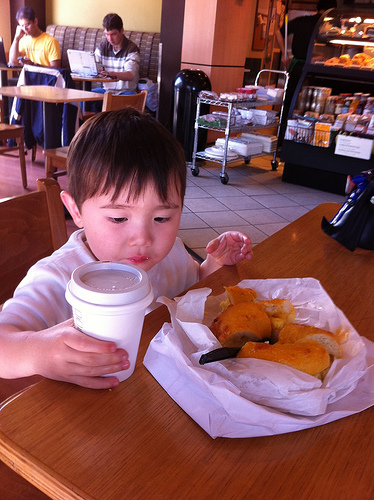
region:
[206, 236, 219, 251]
small child's left thumb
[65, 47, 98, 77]
rear of laptop monitor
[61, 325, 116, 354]
small child's index finger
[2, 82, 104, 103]
small dining table top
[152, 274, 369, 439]
crumpled paper food bag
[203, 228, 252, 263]
small child's left hand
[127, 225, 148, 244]
small asian child's nose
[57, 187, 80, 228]
small child's right ear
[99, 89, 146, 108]
rear of wooden chair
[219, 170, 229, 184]
small black cart wheel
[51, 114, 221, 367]
boy is holding a cup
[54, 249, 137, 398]
the cup has lid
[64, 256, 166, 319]
the lid is white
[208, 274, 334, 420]
bread on the paper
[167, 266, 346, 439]
food on the table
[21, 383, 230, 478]
the table is wooden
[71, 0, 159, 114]
man is using a laptop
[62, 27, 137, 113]
laptop on the table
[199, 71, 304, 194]
containers in the cart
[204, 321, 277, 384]
bread knife is black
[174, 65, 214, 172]
A black shiny garbage bin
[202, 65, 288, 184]
A silver food cart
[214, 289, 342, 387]
A sandwhich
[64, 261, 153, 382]
A white sip cup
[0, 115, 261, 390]
A young boy in a white shirt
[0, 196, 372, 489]
A wooden shiny dinner table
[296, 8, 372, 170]
Refrigerated food stuff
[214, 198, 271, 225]
Grey tile floor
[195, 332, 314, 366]
A serrated knife for cutting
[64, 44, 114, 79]
A laptop computer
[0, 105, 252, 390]
Child holding white cup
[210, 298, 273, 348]
Bread on white bag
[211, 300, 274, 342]
Bread next to bread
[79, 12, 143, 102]
Man on laptop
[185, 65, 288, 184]
Silver metal cart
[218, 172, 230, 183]
Small black wheel on silver metal cart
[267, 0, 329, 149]
Person wearing black shirt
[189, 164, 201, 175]
Small black wheel on silver metal cart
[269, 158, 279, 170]
Small black wheel on silver metal cart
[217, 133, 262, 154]
White box on silver metal cart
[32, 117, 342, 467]
a kid taking his breakfast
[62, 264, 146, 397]
a glass of orange juice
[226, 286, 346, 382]
a couple of delicious bread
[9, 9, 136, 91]
two men connected using their laptops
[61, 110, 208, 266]
a child with asian features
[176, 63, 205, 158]
a large trash can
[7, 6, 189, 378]
threee people doing different things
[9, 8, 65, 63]
a man in a yellow t-shirt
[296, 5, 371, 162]
different kind of delicious food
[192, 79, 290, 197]
a cart full of food